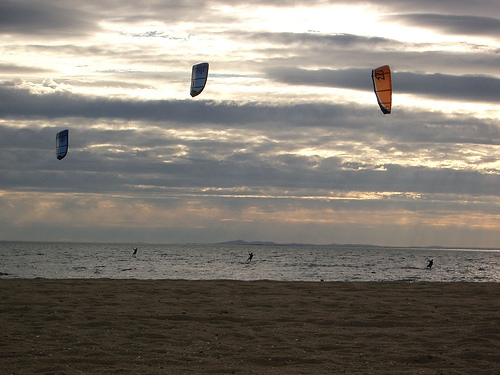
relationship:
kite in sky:
[362, 56, 405, 125] [2, 159, 498, 238]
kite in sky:
[371, 64, 392, 115] [2, 5, 499, 245]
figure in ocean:
[248, 252, 254, 261] [0, 240, 500, 282]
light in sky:
[92, 68, 174, 105] [2, 5, 499, 245]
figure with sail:
[132, 248, 137, 255] [48, 119, 72, 161]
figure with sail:
[248, 252, 254, 261] [177, 43, 232, 145]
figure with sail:
[426, 259, 432, 269] [369, 62, 400, 117]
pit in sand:
[131, 331, 173, 339] [6, 278, 498, 373]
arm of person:
[246, 249, 254, 257] [422, 255, 437, 270]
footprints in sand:
[1, 277, 498, 372] [0, 278, 499, 375]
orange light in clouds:
[0, 189, 499, 232] [2, 1, 498, 193]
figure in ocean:
[426, 259, 432, 269] [1, 240, 498, 372]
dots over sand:
[85, 340, 250, 363] [6, 278, 498, 373]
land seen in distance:
[210, 237, 449, 254] [3, 232, 484, 255]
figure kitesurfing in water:
[132, 248, 137, 255] [1, 239, 484, 282]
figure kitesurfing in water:
[248, 252, 254, 261] [1, 239, 484, 282]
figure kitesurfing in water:
[426, 259, 432, 269] [1, 239, 484, 282]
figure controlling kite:
[132, 248, 137, 255] [55, 129, 68, 160]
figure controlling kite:
[248, 252, 254, 261] [189, 62, 209, 98]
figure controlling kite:
[426, 259, 432, 269] [371, 64, 392, 115]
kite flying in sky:
[55, 129, 68, 160] [2, 5, 499, 245]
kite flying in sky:
[189, 62, 209, 98] [2, 5, 499, 245]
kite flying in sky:
[371, 64, 392, 115] [2, 5, 499, 245]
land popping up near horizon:
[221, 239, 499, 249] [4, 230, 499, 276]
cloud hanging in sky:
[210, 28, 485, 48] [0, 0, 499, 280]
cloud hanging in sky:
[1, 77, 484, 147] [0, 0, 499, 280]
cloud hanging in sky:
[1, 121, 258, 152] [0, 0, 499, 280]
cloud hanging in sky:
[1, 0, 111, 38] [0, 0, 499, 280]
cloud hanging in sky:
[118, 181, 364, 198] [0, 0, 499, 280]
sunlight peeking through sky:
[274, 147, 346, 157] [0, 0, 499, 280]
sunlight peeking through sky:
[183, 187, 420, 201] [0, 0, 499, 280]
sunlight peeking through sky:
[211, 1, 483, 50] [0, 0, 499, 280]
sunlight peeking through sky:
[3, 32, 287, 52] [0, 0, 499, 280]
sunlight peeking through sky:
[105, 147, 125, 154] [0, 0, 499, 280]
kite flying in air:
[55, 129, 68, 160] [1, 1, 484, 245]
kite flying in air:
[189, 62, 209, 98] [1, 1, 484, 245]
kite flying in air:
[371, 64, 392, 115] [1, 1, 484, 245]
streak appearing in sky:
[2, 220, 484, 249] [2, 5, 499, 245]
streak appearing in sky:
[0, 199, 484, 226] [2, 5, 499, 245]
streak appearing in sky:
[42, 190, 484, 210] [2, 5, 499, 245]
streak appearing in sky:
[130, 190, 380, 200] [2, 5, 499, 245]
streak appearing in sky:
[1, 148, 483, 189] [2, 5, 499, 245]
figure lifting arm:
[130, 244, 138, 255] [130, 244, 134, 250]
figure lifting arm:
[245, 249, 255, 261] [247, 250, 251, 255]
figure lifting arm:
[245, 249, 255, 261] [250, 250, 252, 254]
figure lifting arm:
[424, 256, 434, 269] [426, 260, 429, 263]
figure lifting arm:
[424, 256, 434, 269] [428, 258, 430, 260]